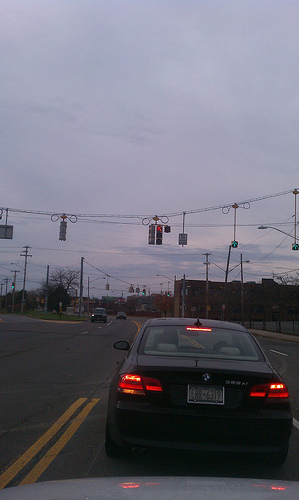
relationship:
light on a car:
[118, 372, 143, 396] [105, 317, 290, 467]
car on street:
[105, 317, 290, 467] [14, 293, 280, 469]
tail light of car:
[268, 381, 288, 399] [105, 317, 290, 467]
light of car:
[118, 372, 162, 396] [105, 317, 290, 467]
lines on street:
[0, 393, 86, 489] [1, 311, 298, 487]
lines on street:
[18, 394, 99, 485] [1, 311, 298, 487]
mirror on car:
[110, 332, 135, 357] [112, 293, 288, 460]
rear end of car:
[118, 363, 289, 456] [105, 317, 290, 467]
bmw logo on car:
[199, 371, 211, 384] [105, 317, 290, 467]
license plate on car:
[188, 383, 221, 405] [105, 317, 290, 467]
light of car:
[184, 322, 216, 332] [108, 304, 288, 468]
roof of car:
[144, 316, 247, 333] [105, 317, 290, 467]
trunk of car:
[134, 353, 273, 392] [105, 317, 290, 467]